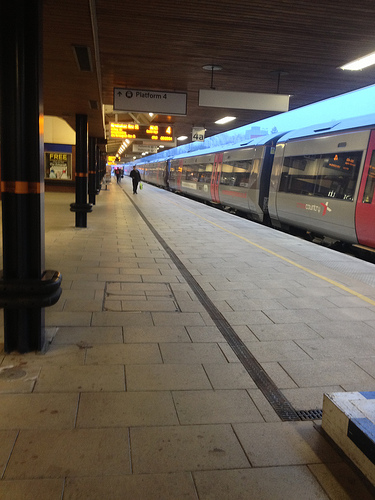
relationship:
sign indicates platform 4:
[109, 86, 194, 122] [136, 90, 169, 100]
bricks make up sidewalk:
[115, 253, 173, 285] [4, 147, 373, 499]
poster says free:
[43, 148, 81, 189] [47, 151, 73, 162]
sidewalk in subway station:
[4, 147, 373, 499] [2, 3, 372, 500]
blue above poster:
[44, 139, 79, 156] [43, 148, 81, 189]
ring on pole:
[4, 175, 51, 198] [3, 2, 54, 360]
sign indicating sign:
[109, 118, 180, 146] [109, 121, 176, 143]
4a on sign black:
[191, 131, 208, 144] [198, 132, 201, 137]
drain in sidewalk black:
[290, 395, 326, 427] [198, 132, 201, 137]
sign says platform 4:
[109, 86, 194, 122] [136, 90, 169, 100]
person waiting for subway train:
[126, 164, 147, 202] [121, 124, 374, 248]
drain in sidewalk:
[290, 395, 326, 427] [4, 147, 373, 499]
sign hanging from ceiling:
[109, 86, 194, 122] [44, 4, 374, 148]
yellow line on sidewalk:
[157, 184, 374, 314] [4, 147, 373, 499]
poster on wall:
[43, 148, 81, 189] [42, 116, 82, 204]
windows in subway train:
[183, 157, 257, 194] [121, 124, 374, 248]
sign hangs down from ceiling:
[109, 86, 194, 122] [44, 4, 374, 148]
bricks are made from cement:
[115, 253, 173, 285] [254, 320, 291, 341]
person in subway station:
[126, 164, 147, 202] [2, 3, 372, 500]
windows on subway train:
[183, 157, 257, 194] [121, 124, 374, 248]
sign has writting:
[109, 86, 194, 122] [117, 89, 176, 103]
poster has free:
[43, 148, 81, 189] [49, 153, 68, 161]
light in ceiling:
[329, 49, 374, 81] [44, 4, 374, 148]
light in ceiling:
[209, 115, 236, 131] [44, 4, 374, 148]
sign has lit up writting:
[109, 118, 180, 146] [116, 121, 173, 137]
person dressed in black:
[126, 164, 147, 202] [198, 132, 201, 137]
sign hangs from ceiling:
[109, 86, 194, 122] [44, 4, 374, 148]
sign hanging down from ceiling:
[198, 89, 292, 114] [44, 4, 374, 148]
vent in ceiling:
[75, 39, 94, 79] [44, 4, 374, 148]